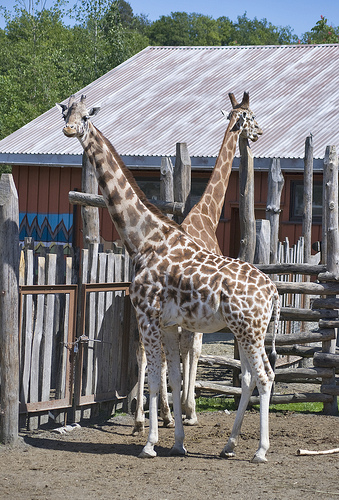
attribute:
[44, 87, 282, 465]
giraffe — looking, brown, white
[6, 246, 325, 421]
fence — wood, wooden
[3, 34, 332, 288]
building — metal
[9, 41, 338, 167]
metal — gray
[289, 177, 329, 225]
window — glass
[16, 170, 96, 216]
wall — red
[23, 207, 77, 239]
painting — blue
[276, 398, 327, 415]
grass — green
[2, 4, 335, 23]
sky — blue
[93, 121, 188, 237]
mane — brown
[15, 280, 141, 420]
gate — metal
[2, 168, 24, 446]
post — grey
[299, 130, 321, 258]
wood — grey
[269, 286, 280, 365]
tail — black, brown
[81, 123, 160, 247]
neck — long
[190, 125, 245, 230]
mane — long, brown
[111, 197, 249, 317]
spots — brown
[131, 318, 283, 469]
legs — long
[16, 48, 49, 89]
leaves — green